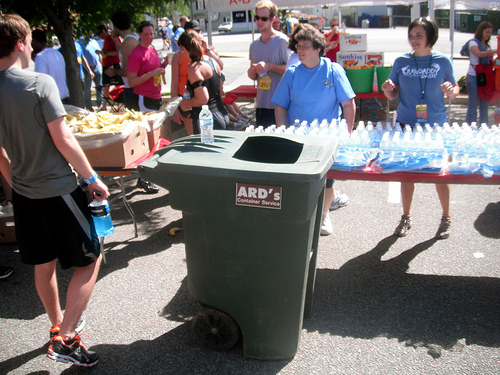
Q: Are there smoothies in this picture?
A: No, there are no smoothies.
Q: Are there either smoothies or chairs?
A: No, there are no smoothies or chairs.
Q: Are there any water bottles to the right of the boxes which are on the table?
A: Yes, there is a water bottle to the right of the boxes.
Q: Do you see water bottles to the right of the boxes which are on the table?
A: Yes, there is a water bottle to the right of the boxes.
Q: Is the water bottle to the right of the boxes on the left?
A: Yes, the water bottle is to the right of the boxes.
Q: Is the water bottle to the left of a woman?
A: Yes, the water bottle is to the left of a woman.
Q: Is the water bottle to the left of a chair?
A: No, the water bottle is to the left of a woman.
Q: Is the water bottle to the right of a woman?
A: No, the water bottle is to the left of a woman.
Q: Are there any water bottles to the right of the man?
A: Yes, there is a water bottle to the right of the man.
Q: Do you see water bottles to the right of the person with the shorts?
A: Yes, there is a water bottle to the right of the man.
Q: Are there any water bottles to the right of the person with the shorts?
A: Yes, there is a water bottle to the right of the man.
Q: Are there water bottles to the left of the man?
A: No, the water bottle is to the right of the man.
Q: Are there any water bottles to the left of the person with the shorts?
A: No, the water bottle is to the right of the man.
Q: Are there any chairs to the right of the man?
A: No, there is a water bottle to the right of the man.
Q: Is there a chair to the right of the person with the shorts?
A: No, there is a water bottle to the right of the man.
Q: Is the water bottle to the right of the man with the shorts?
A: Yes, the water bottle is to the right of the man.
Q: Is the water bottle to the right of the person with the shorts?
A: Yes, the water bottle is to the right of the man.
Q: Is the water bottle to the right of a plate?
A: No, the water bottle is to the right of the man.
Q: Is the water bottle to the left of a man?
A: No, the water bottle is to the right of a man.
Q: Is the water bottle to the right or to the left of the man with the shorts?
A: The water bottle is to the right of the man.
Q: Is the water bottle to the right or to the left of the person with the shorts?
A: The water bottle is to the right of the man.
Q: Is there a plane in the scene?
A: No, there are no airplanes.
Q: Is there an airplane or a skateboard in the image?
A: No, there are no airplanes or skateboards.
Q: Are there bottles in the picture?
A: Yes, there is a bottle.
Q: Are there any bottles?
A: Yes, there is a bottle.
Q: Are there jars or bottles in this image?
A: Yes, there is a bottle.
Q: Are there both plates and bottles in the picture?
A: No, there is a bottle but no plates.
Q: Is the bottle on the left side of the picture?
A: Yes, the bottle is on the left of the image.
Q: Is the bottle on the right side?
A: No, the bottle is on the left of the image.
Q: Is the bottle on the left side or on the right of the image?
A: The bottle is on the left of the image.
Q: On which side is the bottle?
A: The bottle is on the left of the image.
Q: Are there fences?
A: No, there are no fences.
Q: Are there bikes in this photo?
A: No, there are no bikes.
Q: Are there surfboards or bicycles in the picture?
A: No, there are no bicycles or surfboards.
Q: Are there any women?
A: Yes, there is a woman.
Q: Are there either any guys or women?
A: Yes, there is a woman.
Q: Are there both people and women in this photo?
A: Yes, there are both a woman and a person.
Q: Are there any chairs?
A: No, there are no chairs.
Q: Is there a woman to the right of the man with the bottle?
A: Yes, there is a woman to the right of the man.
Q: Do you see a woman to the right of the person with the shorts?
A: Yes, there is a woman to the right of the man.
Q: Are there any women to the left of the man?
A: No, the woman is to the right of the man.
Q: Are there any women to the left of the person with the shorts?
A: No, the woman is to the right of the man.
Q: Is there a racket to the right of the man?
A: No, there is a woman to the right of the man.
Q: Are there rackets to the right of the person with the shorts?
A: No, there is a woman to the right of the man.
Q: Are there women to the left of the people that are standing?
A: Yes, there is a woman to the left of the people.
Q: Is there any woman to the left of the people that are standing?
A: Yes, there is a woman to the left of the people.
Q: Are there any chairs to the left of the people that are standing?
A: No, there is a woman to the left of the people.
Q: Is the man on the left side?
A: Yes, the man is on the left of the image.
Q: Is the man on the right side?
A: No, the man is on the left of the image.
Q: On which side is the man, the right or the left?
A: The man is on the left of the image.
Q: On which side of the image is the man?
A: The man is on the left of the image.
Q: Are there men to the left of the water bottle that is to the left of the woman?
A: Yes, there is a man to the left of the water bottle.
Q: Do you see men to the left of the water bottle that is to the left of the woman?
A: Yes, there is a man to the left of the water bottle.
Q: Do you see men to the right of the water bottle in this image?
A: No, the man is to the left of the water bottle.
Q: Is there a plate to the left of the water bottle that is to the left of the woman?
A: No, there is a man to the left of the water bottle.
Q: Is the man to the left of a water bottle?
A: Yes, the man is to the left of a water bottle.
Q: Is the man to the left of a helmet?
A: No, the man is to the left of a water bottle.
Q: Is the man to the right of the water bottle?
A: No, the man is to the left of the water bottle.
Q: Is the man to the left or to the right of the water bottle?
A: The man is to the left of the water bottle.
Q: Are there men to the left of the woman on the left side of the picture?
A: Yes, there is a man to the left of the woman.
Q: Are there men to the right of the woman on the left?
A: No, the man is to the left of the woman.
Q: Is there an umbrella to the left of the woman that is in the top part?
A: No, there is a man to the left of the woman.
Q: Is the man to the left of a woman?
A: Yes, the man is to the left of a woman.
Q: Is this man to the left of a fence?
A: No, the man is to the left of a woman.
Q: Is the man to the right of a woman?
A: No, the man is to the left of a woman.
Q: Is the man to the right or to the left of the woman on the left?
A: The man is to the left of the woman.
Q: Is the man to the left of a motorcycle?
A: No, the man is to the left of a woman.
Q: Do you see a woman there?
A: Yes, there is a woman.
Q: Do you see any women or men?
A: Yes, there is a woman.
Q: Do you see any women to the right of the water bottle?
A: Yes, there is a woman to the right of the water bottle.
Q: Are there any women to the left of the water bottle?
A: No, the woman is to the right of the water bottle.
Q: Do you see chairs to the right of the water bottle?
A: No, there is a woman to the right of the water bottle.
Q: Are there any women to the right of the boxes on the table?
A: Yes, there is a woman to the right of the boxes.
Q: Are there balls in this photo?
A: No, there are no balls.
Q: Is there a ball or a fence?
A: No, there are no balls or fences.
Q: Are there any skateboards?
A: No, there are no skateboards.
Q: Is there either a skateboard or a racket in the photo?
A: No, there are no skateboards or rackets.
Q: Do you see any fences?
A: No, there are no fences.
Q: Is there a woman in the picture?
A: Yes, there is a woman.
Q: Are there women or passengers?
A: Yes, there is a woman.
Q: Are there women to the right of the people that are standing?
A: Yes, there is a woman to the right of the people.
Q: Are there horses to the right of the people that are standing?
A: No, there is a woman to the right of the people.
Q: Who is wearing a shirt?
A: The woman is wearing a shirt.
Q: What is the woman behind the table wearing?
A: The woman is wearing a shirt.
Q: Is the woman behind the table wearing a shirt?
A: Yes, the woman is wearing a shirt.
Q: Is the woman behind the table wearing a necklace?
A: No, the woman is wearing a shirt.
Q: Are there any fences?
A: No, there are no fences.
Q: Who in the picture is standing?
A: The people are standing.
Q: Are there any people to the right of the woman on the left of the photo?
A: Yes, there are people to the right of the woman.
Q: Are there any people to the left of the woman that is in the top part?
A: No, the people are to the right of the woman.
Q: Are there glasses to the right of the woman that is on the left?
A: No, there are people to the right of the woman.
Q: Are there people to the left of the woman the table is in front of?
A: Yes, there are people to the left of the woman.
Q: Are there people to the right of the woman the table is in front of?
A: No, the people are to the left of the woman.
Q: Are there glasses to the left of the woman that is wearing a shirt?
A: No, there are people to the left of the woman.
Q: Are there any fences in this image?
A: No, there are no fences.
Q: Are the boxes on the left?
A: Yes, the boxes are on the left of the image.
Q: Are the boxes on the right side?
A: No, the boxes are on the left of the image.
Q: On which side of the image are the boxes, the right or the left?
A: The boxes are on the left of the image.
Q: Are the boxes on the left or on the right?
A: The boxes are on the left of the image.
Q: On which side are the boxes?
A: The boxes are on the left of the image.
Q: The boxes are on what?
A: The boxes are on the table.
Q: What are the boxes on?
A: The boxes are on the table.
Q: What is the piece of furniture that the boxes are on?
A: The piece of furniture is a table.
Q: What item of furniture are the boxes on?
A: The boxes are on the table.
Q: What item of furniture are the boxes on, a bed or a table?
A: The boxes are on a table.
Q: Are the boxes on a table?
A: Yes, the boxes are on a table.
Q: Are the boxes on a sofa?
A: No, the boxes are on a table.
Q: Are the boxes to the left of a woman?
A: Yes, the boxes are to the left of a woman.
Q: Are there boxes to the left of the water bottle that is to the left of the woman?
A: Yes, there are boxes to the left of the water bottle.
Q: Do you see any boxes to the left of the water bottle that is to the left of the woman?
A: Yes, there are boxes to the left of the water bottle.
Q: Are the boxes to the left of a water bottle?
A: Yes, the boxes are to the left of a water bottle.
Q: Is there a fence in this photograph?
A: No, there are no fences.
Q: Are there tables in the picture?
A: Yes, there is a table.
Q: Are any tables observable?
A: Yes, there is a table.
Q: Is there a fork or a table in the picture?
A: Yes, there is a table.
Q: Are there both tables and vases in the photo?
A: No, there is a table but no vases.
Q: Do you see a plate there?
A: No, there are no plates.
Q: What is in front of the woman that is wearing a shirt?
A: The table is in front of the woman.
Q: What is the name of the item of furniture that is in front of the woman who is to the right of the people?
A: The piece of furniture is a table.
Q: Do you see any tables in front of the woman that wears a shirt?
A: Yes, there is a table in front of the woman.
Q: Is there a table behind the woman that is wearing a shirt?
A: No, the table is in front of the woman.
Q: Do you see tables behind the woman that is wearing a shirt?
A: No, the table is in front of the woman.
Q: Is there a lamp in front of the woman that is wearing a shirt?
A: No, there is a table in front of the woman.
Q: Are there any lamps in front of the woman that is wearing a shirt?
A: No, there is a table in front of the woman.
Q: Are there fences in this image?
A: No, there are no fences.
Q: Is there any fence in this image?
A: No, there are no fences.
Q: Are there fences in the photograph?
A: No, there are no fences.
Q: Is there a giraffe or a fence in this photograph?
A: No, there are no fences or giraffes.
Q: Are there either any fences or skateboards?
A: No, there are no fences or skateboards.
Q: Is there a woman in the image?
A: Yes, there is a woman.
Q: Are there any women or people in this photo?
A: Yes, there is a woman.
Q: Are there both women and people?
A: Yes, there are both a woman and people.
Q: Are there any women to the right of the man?
A: Yes, there is a woman to the right of the man.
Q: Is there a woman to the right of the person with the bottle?
A: Yes, there is a woman to the right of the man.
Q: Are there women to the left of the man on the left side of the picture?
A: No, the woman is to the right of the man.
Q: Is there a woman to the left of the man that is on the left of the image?
A: No, the woman is to the right of the man.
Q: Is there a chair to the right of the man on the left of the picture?
A: No, there is a woman to the right of the man.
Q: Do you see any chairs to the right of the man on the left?
A: No, there is a woman to the right of the man.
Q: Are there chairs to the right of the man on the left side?
A: No, there is a woman to the right of the man.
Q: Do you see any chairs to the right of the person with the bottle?
A: No, there is a woman to the right of the man.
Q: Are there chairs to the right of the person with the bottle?
A: No, there is a woman to the right of the man.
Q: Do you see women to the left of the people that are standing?
A: Yes, there is a woman to the left of the people.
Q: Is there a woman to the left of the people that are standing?
A: Yes, there is a woman to the left of the people.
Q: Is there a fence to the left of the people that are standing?
A: No, there is a woman to the left of the people.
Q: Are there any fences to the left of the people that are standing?
A: No, there is a woman to the left of the people.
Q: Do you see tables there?
A: Yes, there is a table.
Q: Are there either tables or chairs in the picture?
A: Yes, there is a table.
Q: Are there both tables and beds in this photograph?
A: No, there is a table but no beds.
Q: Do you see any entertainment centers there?
A: No, there are no entertainment centers.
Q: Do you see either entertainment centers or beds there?
A: No, there are no entertainment centers or beds.